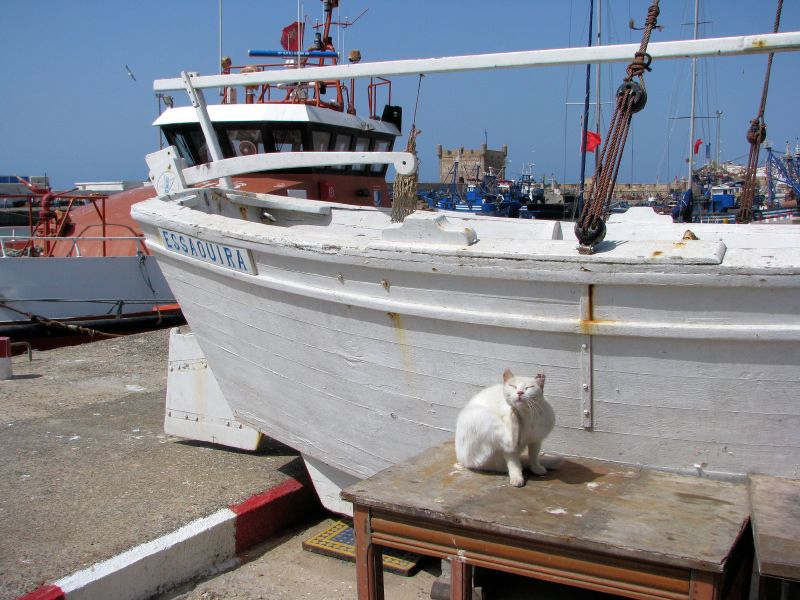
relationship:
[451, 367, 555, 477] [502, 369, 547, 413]
cat scratching neck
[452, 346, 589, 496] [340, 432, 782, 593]
cat on table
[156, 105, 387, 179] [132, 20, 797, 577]
wheel house on boat